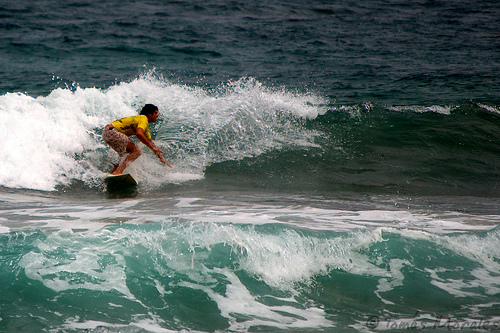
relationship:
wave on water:
[2, 64, 497, 202] [4, 5, 492, 333]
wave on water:
[0, 217, 499, 332] [4, 5, 492, 333]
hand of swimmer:
[151, 147, 167, 156] [99, 101, 173, 177]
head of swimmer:
[137, 102, 163, 122] [99, 101, 173, 177]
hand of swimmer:
[157, 159, 174, 169] [99, 101, 173, 177]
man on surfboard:
[99, 101, 173, 177] [104, 164, 141, 195]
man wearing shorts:
[99, 101, 173, 177] [101, 125, 132, 156]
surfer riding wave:
[99, 101, 173, 177] [2, 64, 497, 202]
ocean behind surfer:
[0, 0, 498, 103] [99, 101, 173, 177]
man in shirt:
[99, 101, 173, 177] [109, 114, 153, 140]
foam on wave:
[2, 74, 314, 184] [2, 64, 497, 202]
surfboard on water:
[104, 164, 141, 195] [4, 5, 492, 333]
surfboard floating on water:
[104, 164, 141, 195] [4, 5, 492, 333]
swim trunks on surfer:
[101, 125, 132, 156] [99, 101, 173, 177]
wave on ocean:
[2, 64, 497, 202] [0, 0, 498, 103]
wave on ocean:
[0, 217, 499, 332] [0, 0, 498, 103]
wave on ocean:
[387, 60, 493, 91] [0, 0, 498, 103]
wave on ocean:
[302, 37, 330, 50] [0, 0, 498, 103]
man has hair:
[99, 101, 173, 177] [141, 105, 158, 115]